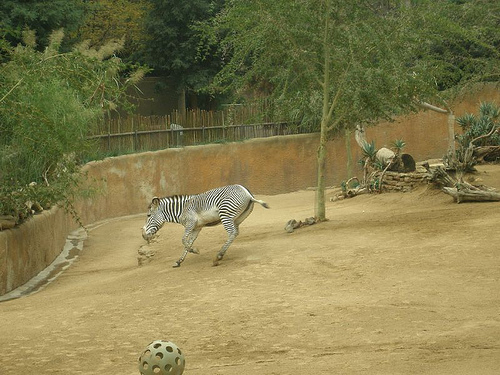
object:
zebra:
[141, 184, 270, 268]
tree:
[189, 1, 446, 223]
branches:
[298, 1, 356, 135]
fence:
[86, 99, 320, 156]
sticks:
[147, 109, 215, 142]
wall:
[3, 82, 499, 299]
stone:
[118, 169, 202, 187]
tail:
[251, 198, 272, 210]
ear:
[152, 197, 160, 207]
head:
[142, 197, 166, 241]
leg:
[218, 212, 240, 256]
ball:
[137, 339, 185, 375]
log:
[442, 179, 499, 205]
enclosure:
[4, 2, 499, 374]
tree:
[131, 0, 237, 112]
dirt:
[1, 159, 500, 374]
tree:
[432, 101, 499, 205]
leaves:
[185, 3, 498, 132]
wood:
[431, 143, 499, 204]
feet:
[172, 249, 224, 268]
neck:
[163, 196, 181, 222]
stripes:
[161, 196, 238, 213]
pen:
[0, 84, 498, 374]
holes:
[155, 351, 164, 359]